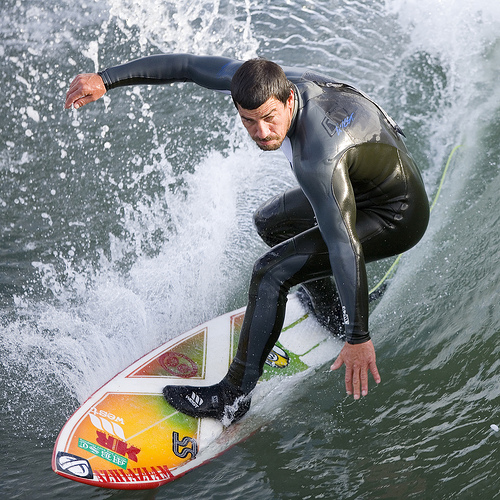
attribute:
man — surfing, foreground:
[56, 44, 439, 427]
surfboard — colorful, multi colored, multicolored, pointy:
[45, 291, 370, 495]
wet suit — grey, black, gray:
[100, 49, 436, 393]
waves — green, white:
[407, 8, 500, 374]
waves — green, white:
[1, 141, 239, 343]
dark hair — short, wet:
[222, 52, 298, 107]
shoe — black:
[160, 374, 257, 425]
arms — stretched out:
[56, 40, 392, 414]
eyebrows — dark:
[237, 106, 280, 124]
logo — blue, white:
[55, 450, 96, 483]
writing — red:
[92, 427, 175, 491]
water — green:
[284, 395, 499, 500]